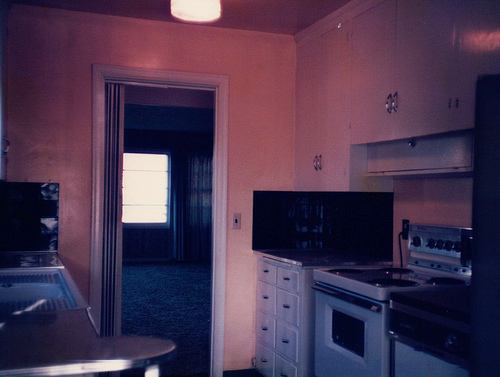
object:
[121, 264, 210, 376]
ground has carpet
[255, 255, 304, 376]
drawers are closed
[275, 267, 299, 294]
drawer is closed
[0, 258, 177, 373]
sink is metalic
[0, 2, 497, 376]
kitchen is clean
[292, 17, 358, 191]
cabinets are above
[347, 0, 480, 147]
cabinets above stove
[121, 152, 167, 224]
light coming through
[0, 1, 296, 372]
pinks on walls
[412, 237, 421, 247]
knob is black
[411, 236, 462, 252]
knobs are black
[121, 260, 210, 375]
carpet is to wall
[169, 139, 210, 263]
carpet is on window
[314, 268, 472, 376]
range is electric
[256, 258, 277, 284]
drawer is kitchen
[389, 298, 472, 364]
dishwasher is auto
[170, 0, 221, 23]
lights for kitchen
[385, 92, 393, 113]
pulls are chrome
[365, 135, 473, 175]
fan is exhaust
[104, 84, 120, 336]
door is pleated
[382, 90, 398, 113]
cabinet has handle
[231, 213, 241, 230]
kitchen has switch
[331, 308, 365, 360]
window on oven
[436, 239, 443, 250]
stove has knob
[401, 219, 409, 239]
kitchen has plug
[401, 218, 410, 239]
plug is on wall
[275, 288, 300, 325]
drawer on cabinet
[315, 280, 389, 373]
door on stove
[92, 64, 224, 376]
doorway has door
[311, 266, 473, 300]
kitchen has stove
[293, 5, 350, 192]
cabinet is white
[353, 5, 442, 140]
cabinet is white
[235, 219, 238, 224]
switch is black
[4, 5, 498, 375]
room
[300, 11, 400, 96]
walls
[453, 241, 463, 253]
knobs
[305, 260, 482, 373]
range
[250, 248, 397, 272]
counter top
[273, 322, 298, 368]
drawers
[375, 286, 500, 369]
dishwasher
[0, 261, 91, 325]
single basin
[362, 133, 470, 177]
exhaust fan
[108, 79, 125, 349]
door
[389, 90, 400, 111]
handles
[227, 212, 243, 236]
switch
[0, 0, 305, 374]
wall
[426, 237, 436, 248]
knobs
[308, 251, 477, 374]
stove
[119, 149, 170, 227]
window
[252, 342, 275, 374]
drawers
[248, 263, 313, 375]
cabinet